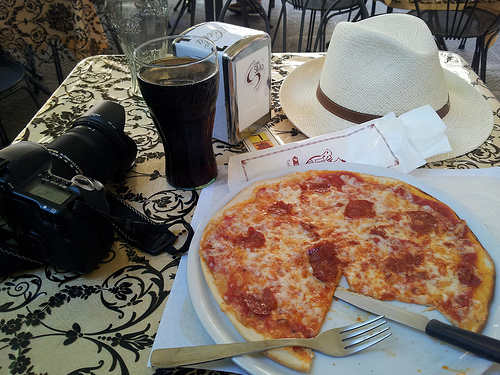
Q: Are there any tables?
A: Yes, there is a table.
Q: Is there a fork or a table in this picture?
A: Yes, there is a table.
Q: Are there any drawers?
A: No, there are no drawers.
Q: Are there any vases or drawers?
A: No, there are no drawers or vases.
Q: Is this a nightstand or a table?
A: This is a table.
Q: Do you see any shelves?
A: No, there are no shelves.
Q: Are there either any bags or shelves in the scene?
A: No, there are no shelves or bags.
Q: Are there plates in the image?
A: Yes, there is a plate.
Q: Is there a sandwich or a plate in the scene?
A: Yes, there is a plate.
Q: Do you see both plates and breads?
A: No, there is a plate but no breads.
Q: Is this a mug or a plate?
A: This is a plate.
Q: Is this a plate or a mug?
A: This is a plate.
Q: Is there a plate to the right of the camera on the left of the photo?
A: Yes, there is a plate to the right of the camera.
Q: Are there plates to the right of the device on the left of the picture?
A: Yes, there is a plate to the right of the camera.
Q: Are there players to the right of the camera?
A: No, there is a plate to the right of the camera.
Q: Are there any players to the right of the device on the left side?
A: No, there is a plate to the right of the camera.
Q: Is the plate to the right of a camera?
A: Yes, the plate is to the right of a camera.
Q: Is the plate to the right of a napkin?
A: No, the plate is to the right of a camera.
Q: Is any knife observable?
A: Yes, there is a knife.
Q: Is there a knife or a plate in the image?
A: Yes, there is a knife.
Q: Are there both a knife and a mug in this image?
A: No, there is a knife but no mugs.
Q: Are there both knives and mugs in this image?
A: No, there is a knife but no mugs.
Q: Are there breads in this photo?
A: No, there are no breads.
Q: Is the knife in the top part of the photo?
A: No, the knife is in the bottom of the image.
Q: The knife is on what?
A: The knife is on the plate.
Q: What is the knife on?
A: The knife is on the plate.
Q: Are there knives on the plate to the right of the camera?
A: Yes, there is a knife on the plate.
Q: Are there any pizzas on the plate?
A: No, there is a knife on the plate.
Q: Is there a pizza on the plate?
A: No, there is a knife on the plate.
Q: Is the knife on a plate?
A: Yes, the knife is on a plate.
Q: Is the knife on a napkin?
A: No, the knife is on a plate.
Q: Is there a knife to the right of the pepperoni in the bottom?
A: Yes, there is a knife to the right of the pepperoni.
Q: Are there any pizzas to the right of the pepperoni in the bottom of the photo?
A: No, there is a knife to the right of the pepperoni.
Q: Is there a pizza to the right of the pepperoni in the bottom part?
A: No, there is a knife to the right of the pepperoni.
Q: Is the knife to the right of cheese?
A: No, the knife is to the right of the pepperoni.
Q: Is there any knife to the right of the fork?
A: Yes, there is a knife to the right of the fork.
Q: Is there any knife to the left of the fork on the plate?
A: No, the knife is to the right of the fork.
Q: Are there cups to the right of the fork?
A: No, there is a knife to the right of the fork.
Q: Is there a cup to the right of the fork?
A: No, there is a knife to the right of the fork.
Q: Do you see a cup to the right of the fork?
A: No, there is a knife to the right of the fork.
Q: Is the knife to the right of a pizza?
A: No, the knife is to the right of a fork.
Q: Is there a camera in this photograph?
A: Yes, there is a camera.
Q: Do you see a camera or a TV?
A: Yes, there is a camera.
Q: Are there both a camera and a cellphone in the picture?
A: No, there is a camera but no cell phones.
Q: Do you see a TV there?
A: No, there are no televisions.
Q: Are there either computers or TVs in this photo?
A: No, there are no TVs or computers.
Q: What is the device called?
A: The device is a camera.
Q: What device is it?
A: The device is a camera.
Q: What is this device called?
A: This is a camera.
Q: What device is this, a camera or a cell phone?
A: This is a camera.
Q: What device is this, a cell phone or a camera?
A: This is a camera.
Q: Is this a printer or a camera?
A: This is a camera.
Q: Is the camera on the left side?
A: Yes, the camera is on the left of the image.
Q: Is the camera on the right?
A: No, the camera is on the left of the image.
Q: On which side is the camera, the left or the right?
A: The camera is on the left of the image.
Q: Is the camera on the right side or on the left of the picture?
A: The camera is on the left of the image.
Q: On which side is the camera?
A: The camera is on the left of the image.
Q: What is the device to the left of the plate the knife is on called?
A: The device is a camera.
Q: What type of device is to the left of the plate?
A: The device is a camera.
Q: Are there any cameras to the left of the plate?
A: Yes, there is a camera to the left of the plate.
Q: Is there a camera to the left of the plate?
A: Yes, there is a camera to the left of the plate.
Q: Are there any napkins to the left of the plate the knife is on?
A: No, there is a camera to the left of the plate.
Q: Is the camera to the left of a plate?
A: Yes, the camera is to the left of a plate.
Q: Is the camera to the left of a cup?
A: No, the camera is to the left of a plate.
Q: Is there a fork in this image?
A: Yes, there is a fork.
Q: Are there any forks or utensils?
A: Yes, there is a fork.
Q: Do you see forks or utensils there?
A: Yes, there is a fork.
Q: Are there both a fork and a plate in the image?
A: Yes, there are both a fork and a plate.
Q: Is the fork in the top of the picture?
A: No, the fork is in the bottom of the image.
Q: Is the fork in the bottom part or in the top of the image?
A: The fork is in the bottom of the image.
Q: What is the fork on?
A: The fork is on the plate.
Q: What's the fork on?
A: The fork is on the plate.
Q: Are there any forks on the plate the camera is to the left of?
A: Yes, there is a fork on the plate.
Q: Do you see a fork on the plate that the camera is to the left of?
A: Yes, there is a fork on the plate.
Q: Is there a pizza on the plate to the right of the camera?
A: No, there is a fork on the plate.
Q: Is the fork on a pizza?
A: No, the fork is on the plate.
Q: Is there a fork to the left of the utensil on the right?
A: Yes, there is a fork to the left of the knife.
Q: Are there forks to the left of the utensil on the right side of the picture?
A: Yes, there is a fork to the left of the knife.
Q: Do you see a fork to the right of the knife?
A: No, the fork is to the left of the knife.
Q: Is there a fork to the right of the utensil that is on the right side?
A: No, the fork is to the left of the knife.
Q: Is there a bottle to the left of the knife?
A: No, there is a fork to the left of the knife.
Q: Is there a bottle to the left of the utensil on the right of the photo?
A: No, there is a fork to the left of the knife.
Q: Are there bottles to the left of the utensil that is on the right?
A: No, there is a fork to the left of the knife.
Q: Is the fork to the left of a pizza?
A: No, the fork is to the left of the knife.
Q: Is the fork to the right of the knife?
A: No, the fork is to the left of the knife.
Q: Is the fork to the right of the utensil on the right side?
A: No, the fork is to the left of the knife.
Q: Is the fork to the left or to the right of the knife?
A: The fork is to the left of the knife.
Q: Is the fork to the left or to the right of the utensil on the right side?
A: The fork is to the left of the knife.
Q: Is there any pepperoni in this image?
A: Yes, there is pepperoni.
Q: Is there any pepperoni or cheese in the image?
A: Yes, there is pepperoni.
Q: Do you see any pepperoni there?
A: Yes, there is pepperoni.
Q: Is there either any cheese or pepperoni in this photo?
A: Yes, there is pepperoni.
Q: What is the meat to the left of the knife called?
A: The meat is pepperoni.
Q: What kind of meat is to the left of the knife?
A: The meat is pepperoni.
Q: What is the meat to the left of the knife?
A: The meat is pepperoni.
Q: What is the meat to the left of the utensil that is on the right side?
A: The meat is pepperoni.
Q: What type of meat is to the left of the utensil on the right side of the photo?
A: The meat is pepperoni.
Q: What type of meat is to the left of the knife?
A: The meat is pepperoni.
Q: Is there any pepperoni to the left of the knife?
A: Yes, there is pepperoni to the left of the knife.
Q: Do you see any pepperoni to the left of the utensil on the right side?
A: Yes, there is pepperoni to the left of the knife.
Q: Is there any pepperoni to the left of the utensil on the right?
A: Yes, there is pepperoni to the left of the knife.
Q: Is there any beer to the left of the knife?
A: No, there is pepperoni to the left of the knife.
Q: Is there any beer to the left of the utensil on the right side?
A: No, there is pepperoni to the left of the knife.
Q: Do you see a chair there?
A: Yes, there is a chair.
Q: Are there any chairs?
A: Yes, there is a chair.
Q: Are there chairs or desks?
A: Yes, there is a chair.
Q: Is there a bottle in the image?
A: No, there are no bottles.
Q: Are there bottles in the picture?
A: No, there are no bottles.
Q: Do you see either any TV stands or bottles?
A: No, there are no bottles or TV stands.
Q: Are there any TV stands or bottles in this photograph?
A: No, there are no bottles or TV stands.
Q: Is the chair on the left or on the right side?
A: The chair is on the right of the image.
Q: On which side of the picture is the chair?
A: The chair is on the right of the image.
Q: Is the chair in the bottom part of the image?
A: No, the chair is in the top of the image.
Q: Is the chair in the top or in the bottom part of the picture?
A: The chair is in the top of the image.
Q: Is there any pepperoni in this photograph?
A: Yes, there is pepperoni.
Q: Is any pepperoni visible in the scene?
A: Yes, there is pepperoni.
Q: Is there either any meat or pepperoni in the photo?
A: Yes, there is pepperoni.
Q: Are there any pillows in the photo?
A: No, there are no pillows.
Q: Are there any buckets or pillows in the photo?
A: No, there are no pillows or buckets.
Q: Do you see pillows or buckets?
A: No, there are no pillows or buckets.